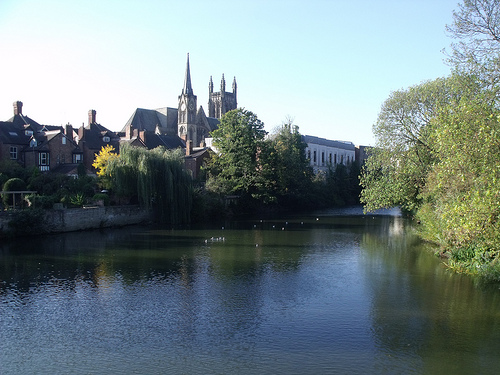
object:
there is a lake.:
[0, 204, 499, 374]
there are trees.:
[198, 108, 280, 210]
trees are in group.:
[91, 106, 319, 219]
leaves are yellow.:
[105, 152, 118, 159]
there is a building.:
[302, 133, 358, 176]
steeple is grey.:
[178, 50, 194, 96]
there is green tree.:
[357, 72, 499, 223]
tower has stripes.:
[180, 112, 187, 124]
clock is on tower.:
[185, 99, 199, 112]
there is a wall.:
[0, 204, 143, 233]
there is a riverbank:
[0, 205, 149, 232]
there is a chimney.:
[11, 97, 24, 118]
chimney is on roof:
[88, 108, 96, 125]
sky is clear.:
[0, 1, 499, 149]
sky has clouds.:
[0, 26, 374, 151]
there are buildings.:
[173, 147, 224, 184]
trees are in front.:
[90, 143, 127, 177]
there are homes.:
[75, 109, 120, 170]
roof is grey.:
[301, 133, 358, 152]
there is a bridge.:
[220, 195, 242, 211]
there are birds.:
[276, 226, 287, 232]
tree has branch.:
[97, 155, 123, 167]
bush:
[0, 175, 33, 211]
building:
[173, 52, 210, 151]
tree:
[99, 141, 197, 218]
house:
[22, 127, 89, 183]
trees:
[399, 95, 499, 285]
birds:
[252, 243, 260, 249]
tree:
[439, 0, 499, 80]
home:
[0, 100, 48, 185]